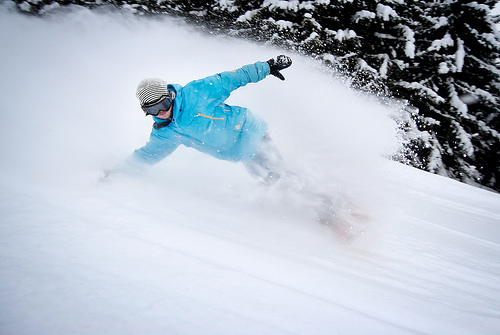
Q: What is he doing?
A: Snowskating.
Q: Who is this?
A: A man.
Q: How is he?
A: In motion.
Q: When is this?
A: Daytime.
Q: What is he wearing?
A: Jacket.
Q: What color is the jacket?
A: Blue.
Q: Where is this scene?
A: On a ski slope.